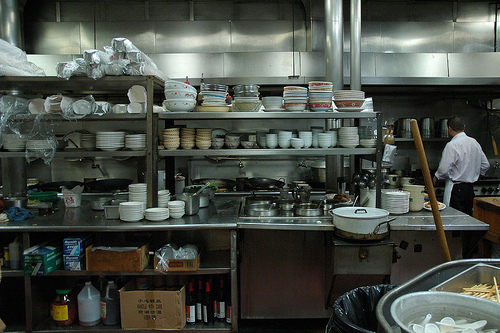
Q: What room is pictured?
A: It is a kitchen.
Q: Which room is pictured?
A: It is a kitchen.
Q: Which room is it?
A: It is a kitchen.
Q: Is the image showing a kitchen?
A: Yes, it is showing a kitchen.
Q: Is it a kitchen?
A: Yes, it is a kitchen.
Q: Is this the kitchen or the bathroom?
A: It is the kitchen.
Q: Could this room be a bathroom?
A: No, it is a kitchen.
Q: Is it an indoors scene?
A: Yes, it is indoors.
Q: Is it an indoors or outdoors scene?
A: It is indoors.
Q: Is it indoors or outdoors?
A: It is indoors.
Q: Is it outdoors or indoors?
A: It is indoors.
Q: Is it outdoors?
A: No, it is indoors.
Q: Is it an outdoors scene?
A: No, it is indoors.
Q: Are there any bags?
A: Yes, there is a bag.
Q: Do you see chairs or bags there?
A: Yes, there is a bag.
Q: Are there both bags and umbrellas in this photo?
A: No, there is a bag but no umbrellas.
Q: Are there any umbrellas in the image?
A: No, there are no umbrellas.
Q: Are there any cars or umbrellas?
A: No, there are no umbrellas or cars.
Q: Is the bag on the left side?
A: No, the bag is on the right of the image.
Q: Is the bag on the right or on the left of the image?
A: The bag is on the right of the image.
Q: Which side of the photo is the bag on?
A: The bag is on the right of the image.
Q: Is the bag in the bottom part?
A: Yes, the bag is in the bottom of the image.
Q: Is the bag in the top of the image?
A: No, the bag is in the bottom of the image.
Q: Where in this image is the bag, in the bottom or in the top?
A: The bag is in the bottom of the image.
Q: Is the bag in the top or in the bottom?
A: The bag is in the bottom of the image.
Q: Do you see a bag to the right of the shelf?
A: Yes, there is a bag to the right of the shelf.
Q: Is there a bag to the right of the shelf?
A: Yes, there is a bag to the right of the shelf.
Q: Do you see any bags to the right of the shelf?
A: Yes, there is a bag to the right of the shelf.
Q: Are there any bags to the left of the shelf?
A: No, the bag is to the right of the shelf.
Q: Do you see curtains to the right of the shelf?
A: No, there is a bag to the right of the shelf.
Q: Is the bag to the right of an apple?
A: No, the bag is to the right of the shelf.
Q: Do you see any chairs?
A: No, there are no chairs.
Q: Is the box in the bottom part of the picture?
A: Yes, the box is in the bottom of the image.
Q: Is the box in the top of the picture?
A: No, the box is in the bottom of the image.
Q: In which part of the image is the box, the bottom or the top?
A: The box is in the bottom of the image.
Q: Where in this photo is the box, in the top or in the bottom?
A: The box is in the bottom of the image.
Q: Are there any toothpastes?
A: No, there are no toothpastes.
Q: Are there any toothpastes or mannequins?
A: No, there are no toothpastes or mannequins.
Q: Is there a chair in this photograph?
A: No, there are no chairs.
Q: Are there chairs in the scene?
A: No, there are no chairs.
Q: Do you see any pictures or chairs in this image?
A: No, there are no chairs or pictures.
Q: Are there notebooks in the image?
A: No, there are no notebooks.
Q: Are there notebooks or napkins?
A: No, there are no notebooks or napkins.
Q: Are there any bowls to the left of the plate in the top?
A: Yes, there are bowls to the left of the plate.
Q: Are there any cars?
A: No, there are no cars.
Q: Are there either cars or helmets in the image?
A: No, there are no cars or helmets.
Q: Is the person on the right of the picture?
A: Yes, the person is on the right of the image.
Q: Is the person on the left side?
A: No, the person is on the right of the image.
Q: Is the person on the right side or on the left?
A: The person is on the right of the image.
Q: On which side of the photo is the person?
A: The person is on the right of the image.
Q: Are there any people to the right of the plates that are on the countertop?
A: Yes, there is a person to the right of the plates.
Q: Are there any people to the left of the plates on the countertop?
A: No, the person is to the right of the plates.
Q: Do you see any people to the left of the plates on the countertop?
A: No, the person is to the right of the plates.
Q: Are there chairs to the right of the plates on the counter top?
A: No, there is a person to the right of the plates.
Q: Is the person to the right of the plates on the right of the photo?
A: Yes, the person is to the right of the plates.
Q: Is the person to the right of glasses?
A: No, the person is to the right of the plates.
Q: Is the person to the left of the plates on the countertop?
A: No, the person is to the right of the plates.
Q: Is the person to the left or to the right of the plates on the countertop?
A: The person is to the right of the plates.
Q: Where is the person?
A: The person is in the kitchen.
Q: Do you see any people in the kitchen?
A: Yes, there is a person in the kitchen.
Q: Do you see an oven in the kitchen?
A: No, there is a person in the kitchen.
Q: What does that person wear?
A: The person wears an outfit.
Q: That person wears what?
A: The person wears an outfit.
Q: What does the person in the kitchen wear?
A: The person wears an outfit.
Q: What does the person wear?
A: The person wears an outfit.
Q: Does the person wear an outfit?
A: Yes, the person wears an outfit.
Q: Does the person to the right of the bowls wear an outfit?
A: Yes, the person wears an outfit.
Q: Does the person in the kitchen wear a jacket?
A: No, the person wears an outfit.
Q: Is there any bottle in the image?
A: Yes, there is a bottle.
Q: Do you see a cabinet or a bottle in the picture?
A: Yes, there is a bottle.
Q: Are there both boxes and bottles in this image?
A: Yes, there are both a bottle and a box.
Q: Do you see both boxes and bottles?
A: Yes, there are both a bottle and a box.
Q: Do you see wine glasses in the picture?
A: No, there are no wine glasses.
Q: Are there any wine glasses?
A: No, there are no wine glasses.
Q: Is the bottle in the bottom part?
A: Yes, the bottle is in the bottom of the image.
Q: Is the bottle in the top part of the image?
A: No, the bottle is in the bottom of the image.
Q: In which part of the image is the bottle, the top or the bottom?
A: The bottle is in the bottom of the image.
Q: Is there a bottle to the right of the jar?
A: Yes, there is a bottle to the right of the jar.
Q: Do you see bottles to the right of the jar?
A: Yes, there is a bottle to the right of the jar.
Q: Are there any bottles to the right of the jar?
A: Yes, there is a bottle to the right of the jar.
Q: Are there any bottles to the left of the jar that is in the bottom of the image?
A: No, the bottle is to the right of the jar.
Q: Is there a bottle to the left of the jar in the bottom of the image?
A: No, the bottle is to the right of the jar.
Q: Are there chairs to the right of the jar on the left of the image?
A: No, there is a bottle to the right of the jar.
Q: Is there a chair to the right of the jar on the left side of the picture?
A: No, there is a bottle to the right of the jar.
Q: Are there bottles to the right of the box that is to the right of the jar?
A: Yes, there is a bottle to the right of the box.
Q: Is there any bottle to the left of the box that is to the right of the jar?
A: No, the bottle is to the right of the box.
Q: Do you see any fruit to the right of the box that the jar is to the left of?
A: No, there is a bottle to the right of the box.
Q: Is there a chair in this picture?
A: No, there are no chairs.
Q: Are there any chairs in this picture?
A: No, there are no chairs.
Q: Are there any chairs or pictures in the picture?
A: No, there are no chairs or pictures.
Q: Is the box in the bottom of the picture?
A: Yes, the box is in the bottom of the image.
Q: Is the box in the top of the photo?
A: No, the box is in the bottom of the image.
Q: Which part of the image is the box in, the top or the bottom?
A: The box is in the bottom of the image.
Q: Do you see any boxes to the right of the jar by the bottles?
A: Yes, there is a box to the right of the jar.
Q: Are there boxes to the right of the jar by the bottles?
A: Yes, there is a box to the right of the jar.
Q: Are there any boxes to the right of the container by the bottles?
A: Yes, there is a box to the right of the jar.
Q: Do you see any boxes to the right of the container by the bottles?
A: Yes, there is a box to the right of the jar.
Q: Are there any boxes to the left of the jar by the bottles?
A: No, the box is to the right of the jar.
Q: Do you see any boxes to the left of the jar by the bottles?
A: No, the box is to the right of the jar.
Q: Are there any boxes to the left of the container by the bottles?
A: No, the box is to the right of the jar.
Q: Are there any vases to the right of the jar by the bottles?
A: No, there is a box to the right of the jar.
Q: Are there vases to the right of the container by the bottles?
A: No, there is a box to the right of the jar.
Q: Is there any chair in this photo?
A: No, there are no chairs.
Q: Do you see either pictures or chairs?
A: No, there are no chairs or pictures.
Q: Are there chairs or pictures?
A: No, there are no chairs or pictures.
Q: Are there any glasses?
A: No, there are no glasses.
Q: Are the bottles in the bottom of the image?
A: Yes, the bottles are in the bottom of the image.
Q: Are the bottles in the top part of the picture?
A: No, the bottles are in the bottom of the image.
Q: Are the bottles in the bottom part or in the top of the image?
A: The bottles are in the bottom of the image.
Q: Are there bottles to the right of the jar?
A: Yes, there are bottles to the right of the jar.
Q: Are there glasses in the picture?
A: No, there are no glasses.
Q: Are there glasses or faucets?
A: No, there are no glasses or faucets.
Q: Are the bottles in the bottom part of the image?
A: Yes, the bottles are in the bottom of the image.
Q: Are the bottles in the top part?
A: No, the bottles are in the bottom of the image.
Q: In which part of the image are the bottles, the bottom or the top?
A: The bottles are in the bottom of the image.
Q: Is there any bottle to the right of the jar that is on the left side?
A: Yes, there are bottles to the right of the jar.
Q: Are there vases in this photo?
A: No, there are no vases.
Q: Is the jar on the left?
A: Yes, the jar is on the left of the image.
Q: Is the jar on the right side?
A: No, the jar is on the left of the image.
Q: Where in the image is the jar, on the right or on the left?
A: The jar is on the left of the image.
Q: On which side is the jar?
A: The jar is on the left of the image.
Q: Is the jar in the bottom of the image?
A: Yes, the jar is in the bottom of the image.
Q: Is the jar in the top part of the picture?
A: No, the jar is in the bottom of the image.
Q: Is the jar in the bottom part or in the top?
A: The jar is in the bottom of the image.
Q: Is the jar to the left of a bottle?
A: Yes, the jar is to the left of a bottle.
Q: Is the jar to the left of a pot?
A: No, the jar is to the left of a bottle.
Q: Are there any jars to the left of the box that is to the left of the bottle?
A: Yes, there is a jar to the left of the box.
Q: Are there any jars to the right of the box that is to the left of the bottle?
A: No, the jar is to the left of the box.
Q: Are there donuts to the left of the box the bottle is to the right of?
A: No, there is a jar to the left of the box.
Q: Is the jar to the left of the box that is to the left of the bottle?
A: Yes, the jar is to the left of the box.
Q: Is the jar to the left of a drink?
A: No, the jar is to the left of the box.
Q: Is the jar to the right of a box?
A: No, the jar is to the left of a box.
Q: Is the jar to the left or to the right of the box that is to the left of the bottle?
A: The jar is to the left of the box.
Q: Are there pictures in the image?
A: No, there are no pictures.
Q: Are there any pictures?
A: No, there are no pictures.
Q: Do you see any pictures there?
A: No, there are no pictures.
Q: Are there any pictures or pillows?
A: No, there are no pictures or pillows.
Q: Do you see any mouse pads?
A: No, there are no mouse pads.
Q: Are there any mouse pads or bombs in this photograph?
A: No, there are no mouse pads or bombs.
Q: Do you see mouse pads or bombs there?
A: No, there are no mouse pads or bombs.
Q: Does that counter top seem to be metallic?
A: Yes, the counter top is metallic.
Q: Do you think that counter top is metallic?
A: Yes, the counter top is metallic.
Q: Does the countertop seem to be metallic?
A: Yes, the countertop is metallic.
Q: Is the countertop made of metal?
A: Yes, the countertop is made of metal.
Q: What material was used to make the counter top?
A: The counter top is made of metal.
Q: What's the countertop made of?
A: The counter top is made of metal.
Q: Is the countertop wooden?
A: No, the countertop is metallic.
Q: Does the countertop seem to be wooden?
A: No, the countertop is metallic.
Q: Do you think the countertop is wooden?
A: No, the countertop is metallic.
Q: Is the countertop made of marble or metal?
A: The countertop is made of metal.